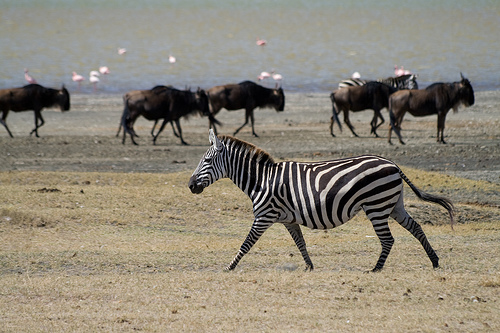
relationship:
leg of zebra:
[280, 220, 316, 272] [187, 137, 461, 317]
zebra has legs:
[183, 127, 456, 272] [223, 215, 445, 276]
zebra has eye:
[183, 127, 456, 272] [201, 152, 213, 167]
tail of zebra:
[384, 158, 462, 239] [183, 127, 456, 272]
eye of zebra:
[200, 157, 215, 165] [162, 115, 472, 304]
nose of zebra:
[187, 176, 199, 187] [183, 127, 453, 272]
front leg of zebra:
[223, 215, 268, 278] [183, 127, 456, 272]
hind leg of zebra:
[365, 200, 395, 272] [169, 109, 474, 291]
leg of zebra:
[390, 195, 440, 268] [183, 127, 453, 272]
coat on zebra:
[201, 140, 444, 267] [183, 127, 453, 272]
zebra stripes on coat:
[290, 167, 349, 214] [201, 140, 444, 267]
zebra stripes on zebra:
[290, 167, 349, 214] [183, 127, 453, 272]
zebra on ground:
[183, 127, 453, 272] [0, 89, 499, 333]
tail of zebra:
[393, 166, 457, 232] [183, 127, 456, 272]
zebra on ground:
[183, 127, 456, 272] [13, 234, 498, 329]